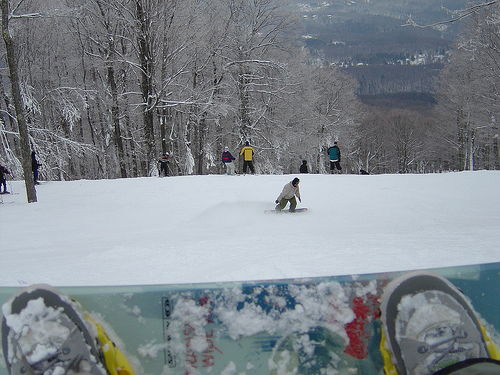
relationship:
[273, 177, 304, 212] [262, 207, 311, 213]
person on board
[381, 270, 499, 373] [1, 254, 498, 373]
sneaker on snowboard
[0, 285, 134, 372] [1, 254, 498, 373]
sneaker on snowboard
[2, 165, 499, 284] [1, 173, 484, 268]
snow on ground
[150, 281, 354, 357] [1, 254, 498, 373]
snow on snowboard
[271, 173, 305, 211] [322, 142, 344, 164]
person wearing green jacket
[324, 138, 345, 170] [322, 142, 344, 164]
person wearing green jacket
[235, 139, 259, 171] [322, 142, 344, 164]
person wearing green jacket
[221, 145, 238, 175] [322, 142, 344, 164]
person wearing green jacket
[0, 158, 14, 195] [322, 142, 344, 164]
person wearing green jacket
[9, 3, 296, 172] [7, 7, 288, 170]
snow on tree branches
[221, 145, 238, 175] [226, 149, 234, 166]
person with jacket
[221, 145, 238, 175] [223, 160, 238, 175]
person with pants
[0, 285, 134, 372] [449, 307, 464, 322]
sneaker with snow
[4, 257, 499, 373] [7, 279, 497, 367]
snow board with shoes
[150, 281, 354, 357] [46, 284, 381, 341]
snow on snowboard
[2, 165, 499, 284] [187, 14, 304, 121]
snow on tree branches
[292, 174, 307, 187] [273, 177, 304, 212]
black hat on person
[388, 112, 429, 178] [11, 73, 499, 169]
tree in field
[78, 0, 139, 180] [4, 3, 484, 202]
tree in field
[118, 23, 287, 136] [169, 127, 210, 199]
tree branches with snow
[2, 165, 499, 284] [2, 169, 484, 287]
snow covering ski surface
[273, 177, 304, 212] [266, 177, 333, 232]
person skiing on board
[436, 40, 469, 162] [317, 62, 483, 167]
tree standing in field